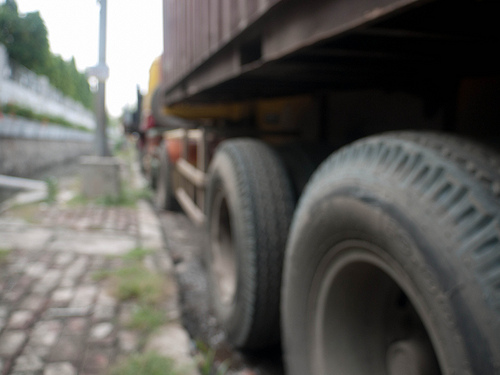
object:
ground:
[0, 122, 224, 373]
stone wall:
[0, 59, 96, 174]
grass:
[0, 146, 196, 375]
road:
[157, 152, 259, 374]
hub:
[209, 202, 238, 309]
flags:
[76, 0, 122, 200]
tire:
[281, 135, 498, 375]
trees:
[0, 6, 24, 81]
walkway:
[3, 148, 199, 375]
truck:
[122, 55, 171, 204]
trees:
[22, 15, 51, 72]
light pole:
[92, 1, 107, 156]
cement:
[2, 116, 195, 373]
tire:
[199, 134, 298, 365]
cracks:
[36, 265, 69, 311]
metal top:
[157, 2, 349, 112]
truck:
[160, 2, 496, 370]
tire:
[154, 145, 174, 210]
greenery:
[0, 103, 100, 137]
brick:
[0, 140, 35, 175]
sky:
[15, 1, 165, 110]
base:
[76, 155, 122, 203]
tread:
[298, 133, 499, 232]